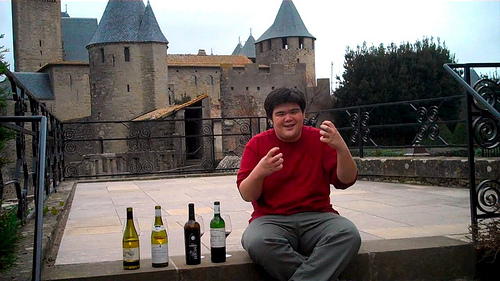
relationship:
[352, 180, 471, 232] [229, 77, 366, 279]
platform behind man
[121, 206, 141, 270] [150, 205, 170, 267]
bottle on bottle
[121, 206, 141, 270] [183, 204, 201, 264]
bottle on bottle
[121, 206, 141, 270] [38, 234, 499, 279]
bottle on step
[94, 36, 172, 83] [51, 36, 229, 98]
windows in castle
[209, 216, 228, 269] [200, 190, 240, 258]
side of glass